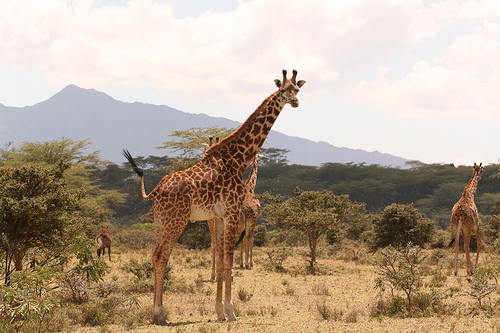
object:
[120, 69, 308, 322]
giraffe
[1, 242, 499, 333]
plain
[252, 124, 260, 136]
spot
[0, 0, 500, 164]
cloud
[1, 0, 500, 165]
sky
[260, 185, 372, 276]
tree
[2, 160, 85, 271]
trees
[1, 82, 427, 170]
mountain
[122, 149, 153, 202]
tail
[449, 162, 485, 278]
giraffe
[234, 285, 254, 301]
grass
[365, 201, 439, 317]
bush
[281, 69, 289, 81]
horn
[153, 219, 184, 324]
leg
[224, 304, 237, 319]
hoves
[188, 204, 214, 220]
belly